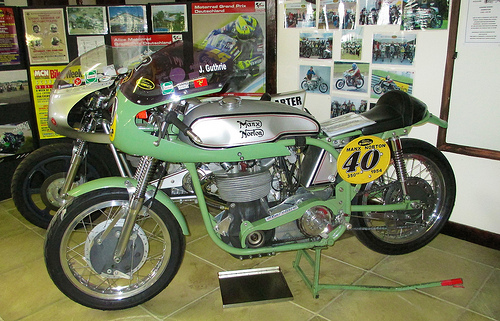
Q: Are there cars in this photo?
A: No, there are no cars.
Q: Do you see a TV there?
A: No, there are no televisions.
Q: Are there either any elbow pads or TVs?
A: No, there are no TVs or elbow pads.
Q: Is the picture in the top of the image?
A: Yes, the picture is in the top of the image.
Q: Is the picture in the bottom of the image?
A: No, the picture is in the top of the image.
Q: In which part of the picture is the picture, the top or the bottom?
A: The picture is in the top of the image.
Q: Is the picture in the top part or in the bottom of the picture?
A: The picture is in the top of the image.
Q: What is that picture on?
A: The picture is on the wall.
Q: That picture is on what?
A: The picture is on the wall.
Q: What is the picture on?
A: The picture is on the wall.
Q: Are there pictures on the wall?
A: Yes, there is a picture on the wall.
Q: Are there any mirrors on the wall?
A: No, there is a picture on the wall.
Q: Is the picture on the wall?
A: Yes, the picture is on the wall.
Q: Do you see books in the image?
A: No, there are no books.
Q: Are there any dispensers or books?
A: No, there are no books or dispensers.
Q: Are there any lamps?
A: No, there are no lamps.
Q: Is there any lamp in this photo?
A: No, there are no lamps.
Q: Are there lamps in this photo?
A: No, there are no lamps.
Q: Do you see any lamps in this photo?
A: No, there are no lamps.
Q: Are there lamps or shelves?
A: No, there are no lamps or shelves.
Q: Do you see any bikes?
A: Yes, there is a bike.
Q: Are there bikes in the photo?
A: Yes, there is a bike.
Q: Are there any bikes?
A: Yes, there is a bike.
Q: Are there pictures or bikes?
A: Yes, there is a bike.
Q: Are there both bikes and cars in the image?
A: No, there is a bike but no cars.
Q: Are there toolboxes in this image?
A: No, there are no toolboxes.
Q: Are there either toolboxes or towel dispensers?
A: No, there are no toolboxes or towel dispensers.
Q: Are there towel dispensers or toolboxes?
A: No, there are no toolboxes or towel dispensers.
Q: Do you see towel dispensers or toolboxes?
A: No, there are no toolboxes or towel dispensers.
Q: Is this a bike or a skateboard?
A: This is a bike.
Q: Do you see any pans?
A: Yes, there is a pan.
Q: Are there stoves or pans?
A: Yes, there is a pan.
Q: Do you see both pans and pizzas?
A: No, there is a pan but no pizzas.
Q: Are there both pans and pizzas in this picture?
A: No, there is a pan but no pizzas.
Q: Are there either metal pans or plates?
A: Yes, there is a metal pan.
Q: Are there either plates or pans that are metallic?
A: Yes, the pan is metallic.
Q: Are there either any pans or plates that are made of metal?
A: Yes, the pan is made of metal.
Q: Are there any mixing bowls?
A: No, there are no mixing bowls.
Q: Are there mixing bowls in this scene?
A: No, there are no mixing bowls.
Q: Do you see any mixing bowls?
A: No, there are no mixing bowls.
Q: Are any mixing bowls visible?
A: No, there are no mixing bowls.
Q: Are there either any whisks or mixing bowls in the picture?
A: No, there are no mixing bowls or whisks.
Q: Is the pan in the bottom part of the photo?
A: Yes, the pan is in the bottom of the image.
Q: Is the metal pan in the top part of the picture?
A: No, the pan is in the bottom of the image.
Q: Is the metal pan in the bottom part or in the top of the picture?
A: The pan is in the bottom of the image.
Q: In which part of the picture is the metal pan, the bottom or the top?
A: The pan is in the bottom of the image.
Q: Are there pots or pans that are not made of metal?
A: No, there is a pan but it is made of metal.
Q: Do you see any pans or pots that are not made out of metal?
A: No, there is a pan but it is made of metal.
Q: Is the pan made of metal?
A: Yes, the pan is made of metal.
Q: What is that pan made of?
A: The pan is made of metal.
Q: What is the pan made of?
A: The pan is made of metal.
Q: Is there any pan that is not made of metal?
A: No, there is a pan but it is made of metal.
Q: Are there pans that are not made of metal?
A: No, there is a pan but it is made of metal.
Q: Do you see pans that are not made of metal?
A: No, there is a pan but it is made of metal.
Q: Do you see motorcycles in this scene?
A: Yes, there is a motorcycle.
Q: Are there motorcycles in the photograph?
A: Yes, there is a motorcycle.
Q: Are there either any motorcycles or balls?
A: Yes, there is a motorcycle.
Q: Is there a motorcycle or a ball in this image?
A: Yes, there is a motorcycle.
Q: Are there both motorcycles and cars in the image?
A: No, there is a motorcycle but no cars.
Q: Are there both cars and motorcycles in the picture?
A: No, there is a motorcycle but no cars.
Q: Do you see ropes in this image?
A: No, there are no ropes.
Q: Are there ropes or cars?
A: No, there are no ropes or cars.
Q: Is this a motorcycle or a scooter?
A: This is a motorcycle.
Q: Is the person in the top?
A: Yes, the person is in the top of the image.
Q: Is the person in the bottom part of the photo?
A: No, the person is in the top of the image.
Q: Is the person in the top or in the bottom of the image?
A: The person is in the top of the image.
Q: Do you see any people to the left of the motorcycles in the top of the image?
A: Yes, there is a person to the left of the motorbikes.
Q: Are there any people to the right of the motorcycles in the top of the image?
A: No, the person is to the left of the motorbikes.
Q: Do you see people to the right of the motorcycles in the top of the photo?
A: No, the person is to the left of the motorbikes.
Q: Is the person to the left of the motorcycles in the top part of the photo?
A: Yes, the person is to the left of the motorbikes.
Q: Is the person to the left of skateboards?
A: No, the person is to the left of the motorbikes.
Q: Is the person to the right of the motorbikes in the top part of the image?
A: No, the person is to the left of the motorbikes.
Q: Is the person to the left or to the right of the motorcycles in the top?
A: The person is to the left of the motorbikes.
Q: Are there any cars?
A: No, there are no cars.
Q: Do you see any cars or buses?
A: No, there are no cars or buses.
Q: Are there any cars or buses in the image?
A: No, there are no cars or buses.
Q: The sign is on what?
A: The sign is on the wall.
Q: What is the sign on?
A: The sign is on the wall.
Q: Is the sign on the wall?
A: Yes, the sign is on the wall.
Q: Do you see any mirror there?
A: No, there are no mirrors.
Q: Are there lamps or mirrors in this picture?
A: No, there are no mirrors or lamps.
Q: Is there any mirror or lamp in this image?
A: No, there are no mirrors or lamps.